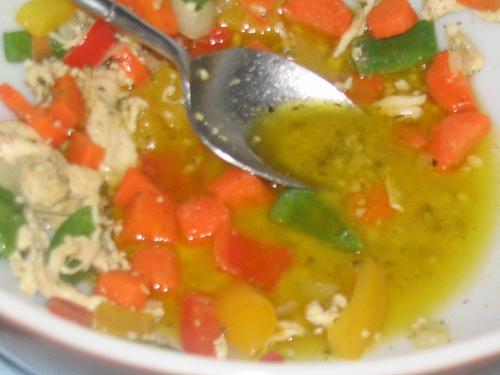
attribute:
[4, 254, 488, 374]
bowl — white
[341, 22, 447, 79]
peppers — green